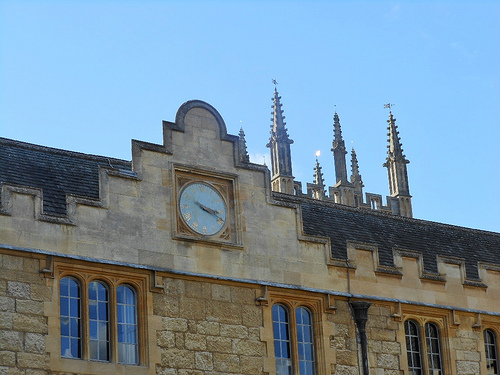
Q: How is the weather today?
A: It is clear.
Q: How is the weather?
A: It is clear.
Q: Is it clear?
A: Yes, it is clear.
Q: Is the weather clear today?
A: Yes, it is clear.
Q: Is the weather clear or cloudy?
A: It is clear.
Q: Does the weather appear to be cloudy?
A: No, it is clear.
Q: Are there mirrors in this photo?
A: No, there are no mirrors.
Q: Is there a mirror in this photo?
A: No, there are no mirrors.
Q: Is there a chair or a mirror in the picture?
A: No, there are no mirrors or chairs.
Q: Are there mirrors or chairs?
A: No, there are no mirrors or chairs.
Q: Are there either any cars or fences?
A: No, there are no cars or fences.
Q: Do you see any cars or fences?
A: No, there are no cars or fences.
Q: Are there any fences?
A: No, there are no fences.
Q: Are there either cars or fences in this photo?
A: No, there are no fences or cars.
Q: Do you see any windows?
A: Yes, there is a window.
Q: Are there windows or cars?
A: Yes, there is a window.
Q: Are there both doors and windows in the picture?
A: No, there is a window but no doors.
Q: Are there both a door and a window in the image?
A: No, there is a window but no doors.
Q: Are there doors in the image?
A: No, there are no doors.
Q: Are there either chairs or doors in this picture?
A: No, there are no doors or chairs.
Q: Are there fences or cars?
A: No, there are no fences or cars.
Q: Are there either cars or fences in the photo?
A: No, there are no fences or cars.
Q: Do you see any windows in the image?
A: Yes, there is a window.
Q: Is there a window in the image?
A: Yes, there is a window.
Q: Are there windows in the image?
A: Yes, there is a window.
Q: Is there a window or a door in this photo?
A: Yes, there is a window.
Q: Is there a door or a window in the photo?
A: Yes, there is a window.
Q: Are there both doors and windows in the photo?
A: No, there is a window but no doors.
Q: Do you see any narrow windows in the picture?
A: Yes, there is a narrow window.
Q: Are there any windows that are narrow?
A: Yes, there is a window that is narrow.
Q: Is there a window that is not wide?
A: Yes, there is a narrow window.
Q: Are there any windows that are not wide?
A: Yes, there is a narrow window.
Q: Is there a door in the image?
A: No, there are no doors.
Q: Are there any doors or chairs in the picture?
A: No, there are no doors or chairs.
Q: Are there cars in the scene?
A: No, there are no cars.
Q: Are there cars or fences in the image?
A: No, there are no cars or fences.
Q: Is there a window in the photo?
A: Yes, there is a window.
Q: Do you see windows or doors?
A: Yes, there is a window.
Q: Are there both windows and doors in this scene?
A: No, there is a window but no doors.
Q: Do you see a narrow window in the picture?
A: Yes, there is a narrow window.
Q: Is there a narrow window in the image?
A: Yes, there is a narrow window.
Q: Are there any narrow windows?
A: Yes, there is a narrow window.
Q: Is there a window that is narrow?
A: Yes, there is a window that is narrow.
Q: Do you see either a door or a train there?
A: No, there are no doors or trains.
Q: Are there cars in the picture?
A: No, there are no cars.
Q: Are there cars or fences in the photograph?
A: No, there are no cars or fences.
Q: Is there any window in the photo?
A: Yes, there is a window.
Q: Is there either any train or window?
A: Yes, there is a window.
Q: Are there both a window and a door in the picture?
A: No, there is a window but no doors.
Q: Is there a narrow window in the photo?
A: Yes, there is a narrow window.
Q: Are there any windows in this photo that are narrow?
A: Yes, there is a window that is narrow.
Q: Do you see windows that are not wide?
A: Yes, there is a narrow window.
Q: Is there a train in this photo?
A: No, there are no trains.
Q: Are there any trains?
A: No, there are no trains.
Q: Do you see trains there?
A: No, there are no trains.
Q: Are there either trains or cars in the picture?
A: No, there are no trains or cars.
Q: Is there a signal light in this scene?
A: No, there are no traffic lights.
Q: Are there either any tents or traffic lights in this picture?
A: No, there are no traffic lights or tents.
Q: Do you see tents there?
A: No, there are no tents.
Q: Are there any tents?
A: No, there are no tents.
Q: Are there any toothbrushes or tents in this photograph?
A: No, there are no tents or toothbrushes.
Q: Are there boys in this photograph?
A: No, there are no boys.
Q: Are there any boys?
A: No, there are no boys.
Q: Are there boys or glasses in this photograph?
A: No, there are no boys or glasses.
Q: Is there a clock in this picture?
A: Yes, there is a clock.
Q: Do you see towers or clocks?
A: Yes, there is a clock.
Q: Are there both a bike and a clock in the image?
A: No, there is a clock but no bikes.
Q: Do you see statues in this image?
A: No, there are no statues.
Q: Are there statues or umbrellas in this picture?
A: No, there are no statues or umbrellas.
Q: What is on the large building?
A: The clock is on the building.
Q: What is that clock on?
A: The clock is on the building.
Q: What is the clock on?
A: The clock is on the building.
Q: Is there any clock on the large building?
A: Yes, there is a clock on the building.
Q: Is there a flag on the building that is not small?
A: No, there is a clock on the building.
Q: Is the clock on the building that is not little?
A: Yes, the clock is on the building.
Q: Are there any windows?
A: Yes, there is a window.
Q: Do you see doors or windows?
A: Yes, there is a window.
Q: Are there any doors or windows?
A: Yes, there is a window.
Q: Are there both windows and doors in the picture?
A: No, there is a window but no doors.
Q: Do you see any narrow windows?
A: Yes, there is a narrow window.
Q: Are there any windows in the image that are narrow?
A: Yes, there is a window that is narrow.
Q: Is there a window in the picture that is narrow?
A: Yes, there is a window that is narrow.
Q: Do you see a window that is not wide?
A: Yes, there is a narrow window.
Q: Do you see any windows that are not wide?
A: Yes, there is a narrow window.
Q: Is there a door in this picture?
A: No, there are no doors.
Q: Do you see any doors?
A: No, there are no doors.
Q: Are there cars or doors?
A: No, there are no doors or cars.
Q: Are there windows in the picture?
A: Yes, there is a window.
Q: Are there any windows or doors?
A: Yes, there is a window.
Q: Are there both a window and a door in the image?
A: No, there is a window but no doors.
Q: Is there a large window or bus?
A: Yes, there is a large window.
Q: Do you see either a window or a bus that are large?
A: Yes, the window is large.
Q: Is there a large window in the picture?
A: Yes, there is a large window.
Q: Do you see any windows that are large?
A: Yes, there is a window that is large.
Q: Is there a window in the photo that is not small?
A: Yes, there is a large window.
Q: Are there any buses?
A: No, there are no buses.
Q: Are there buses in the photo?
A: No, there are no buses.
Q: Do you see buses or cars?
A: No, there are no buses or cars.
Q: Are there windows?
A: Yes, there is a window.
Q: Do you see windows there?
A: Yes, there is a window.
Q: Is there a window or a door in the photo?
A: Yes, there is a window.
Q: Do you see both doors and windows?
A: No, there is a window but no doors.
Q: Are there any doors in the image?
A: No, there are no doors.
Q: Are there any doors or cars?
A: No, there are no doors or cars.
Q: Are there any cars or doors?
A: No, there are no doors or cars.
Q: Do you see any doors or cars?
A: No, there are no doors or cars.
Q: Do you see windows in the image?
A: Yes, there is a window.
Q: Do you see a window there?
A: Yes, there is a window.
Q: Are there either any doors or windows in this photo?
A: Yes, there is a window.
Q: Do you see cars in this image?
A: No, there are no cars.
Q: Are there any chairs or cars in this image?
A: No, there are no cars or chairs.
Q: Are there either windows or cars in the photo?
A: Yes, there is a window.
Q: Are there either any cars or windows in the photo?
A: Yes, there is a window.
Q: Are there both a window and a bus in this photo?
A: No, there is a window but no buses.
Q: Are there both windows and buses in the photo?
A: No, there is a window but no buses.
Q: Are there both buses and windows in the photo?
A: No, there is a window but no buses.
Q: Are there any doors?
A: No, there are no doors.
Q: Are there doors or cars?
A: No, there are no doors or cars.